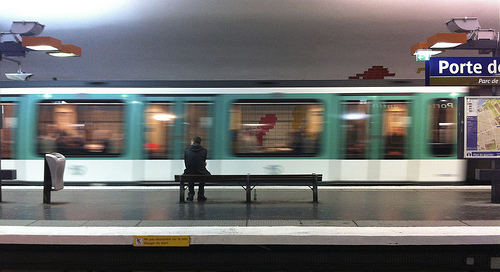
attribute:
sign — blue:
[426, 56, 498, 85]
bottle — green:
[250, 186, 262, 204]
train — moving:
[0, 86, 475, 189]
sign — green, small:
[415, 51, 435, 65]